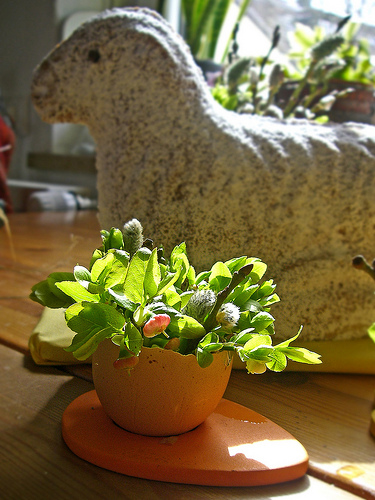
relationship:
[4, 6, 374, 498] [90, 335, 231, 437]
scene shows planter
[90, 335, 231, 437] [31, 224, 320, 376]
planter has plants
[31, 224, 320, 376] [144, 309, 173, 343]
plants include a red blossom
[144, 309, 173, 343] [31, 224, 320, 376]
red blossom part of plants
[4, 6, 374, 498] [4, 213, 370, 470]
scene shows table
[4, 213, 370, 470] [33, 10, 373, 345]
table has on it a sheep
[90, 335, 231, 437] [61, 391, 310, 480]
planter has a base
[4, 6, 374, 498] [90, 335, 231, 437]
scene shows water on planter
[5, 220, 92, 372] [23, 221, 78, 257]
counter has glossy wood surface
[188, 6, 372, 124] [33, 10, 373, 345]
plants are growing behind sheep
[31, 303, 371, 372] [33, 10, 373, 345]
yellow base under sheep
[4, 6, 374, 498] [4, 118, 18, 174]
scene shows hook with red towel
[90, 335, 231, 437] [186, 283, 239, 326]
planter has flower buds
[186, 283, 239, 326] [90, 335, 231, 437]
green flower buds are inside of pot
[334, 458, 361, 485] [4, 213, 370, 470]
water spot on surface of table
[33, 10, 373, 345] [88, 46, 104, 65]
sheep has eye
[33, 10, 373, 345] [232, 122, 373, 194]
sheep shows lines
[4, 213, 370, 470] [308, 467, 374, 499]
table shows split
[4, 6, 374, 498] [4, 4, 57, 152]
scene shows wall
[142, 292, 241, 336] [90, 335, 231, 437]
flowers are inside of clay pot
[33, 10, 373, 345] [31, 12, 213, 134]
sheep has head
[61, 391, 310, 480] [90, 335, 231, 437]
stand beneath planter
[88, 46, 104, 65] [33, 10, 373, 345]
eye part of ornamental sheep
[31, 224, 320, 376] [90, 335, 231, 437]
plants are inside of planter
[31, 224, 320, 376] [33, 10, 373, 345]
plants in planter front sheep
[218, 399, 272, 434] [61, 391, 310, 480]
water on base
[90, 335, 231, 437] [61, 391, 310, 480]
planter rests upon base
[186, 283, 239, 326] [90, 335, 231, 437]
flower buds are leafy inside of planter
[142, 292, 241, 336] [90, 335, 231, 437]
flowers are inside of planter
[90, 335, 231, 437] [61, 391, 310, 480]
planter has ceramic base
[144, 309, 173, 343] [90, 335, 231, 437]
red blossom inside of planter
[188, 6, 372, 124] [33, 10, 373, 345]
plants are behind sheep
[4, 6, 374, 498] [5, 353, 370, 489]
scene shows stain on floor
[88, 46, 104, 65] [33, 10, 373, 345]
eye part of sheep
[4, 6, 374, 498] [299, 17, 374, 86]
scene shows egg holding plant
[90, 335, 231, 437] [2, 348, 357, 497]
planter atop board